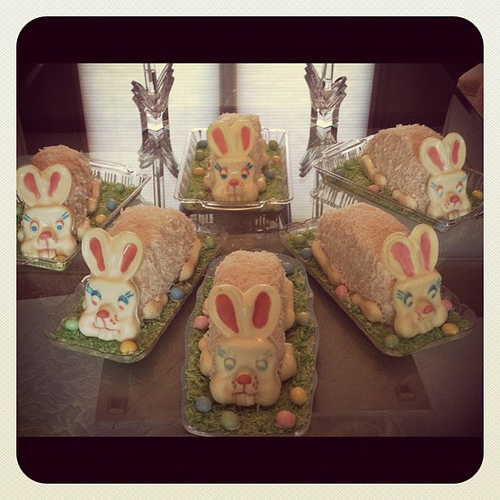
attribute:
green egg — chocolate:
[60, 316, 79, 331]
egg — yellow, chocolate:
[446, 316, 457, 341]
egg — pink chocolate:
[273, 406, 295, 433]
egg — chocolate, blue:
[274, 386, 309, 429]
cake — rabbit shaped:
[195, 245, 299, 406]